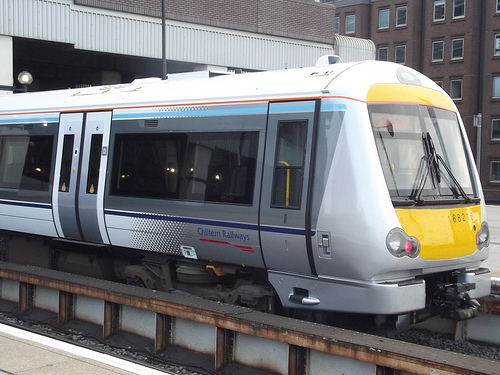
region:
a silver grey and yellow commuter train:
[0, 50, 496, 335]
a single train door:
[259, 100, 319, 276]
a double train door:
[50, 108, 112, 246]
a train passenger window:
[182, 131, 254, 204]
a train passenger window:
[112, 131, 182, 198]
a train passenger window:
[2, 134, 50, 190]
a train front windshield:
[371, 105, 476, 199]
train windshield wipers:
[410, 131, 472, 203]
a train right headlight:
[387, 232, 404, 251]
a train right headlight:
[481, 224, 489, 243]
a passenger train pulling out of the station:
[1, 39, 493, 345]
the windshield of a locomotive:
[369, 107, 476, 202]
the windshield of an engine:
[367, 103, 478, 205]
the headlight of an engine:
[386, 227, 406, 259]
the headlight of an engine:
[473, 218, 489, 247]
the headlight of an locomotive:
[383, 229, 406, 260]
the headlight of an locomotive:
[473, 223, 488, 248]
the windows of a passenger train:
[115, 135, 254, 207]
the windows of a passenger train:
[0, 123, 54, 193]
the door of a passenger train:
[261, 103, 318, 284]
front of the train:
[383, 77, 485, 252]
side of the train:
[12, 102, 315, 279]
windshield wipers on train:
[391, 150, 479, 203]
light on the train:
[370, 210, 410, 269]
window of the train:
[95, 123, 264, 202]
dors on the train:
[55, 90, 110, 249]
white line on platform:
[32, 315, 99, 365]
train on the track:
[5, 212, 475, 362]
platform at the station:
[10, 325, 55, 371]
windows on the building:
[361, 3, 448, 56]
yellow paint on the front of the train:
[346, 70, 491, 285]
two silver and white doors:
[45, 106, 122, 251]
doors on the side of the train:
[45, 105, 121, 250]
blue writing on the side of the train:
[185, 220, 260, 240]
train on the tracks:
[1, 28, 488, 373]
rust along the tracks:
[3, 265, 463, 373]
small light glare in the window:
[209, 168, 224, 183]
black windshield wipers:
[403, 129, 473, 201]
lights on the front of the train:
[381, 225, 425, 256]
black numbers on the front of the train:
[443, 210, 468, 226]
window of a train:
[105, 127, 262, 205]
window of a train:
[272, 119, 307, 209]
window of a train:
[370, 104, 476, 206]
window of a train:
[85, 133, 102, 195]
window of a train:
[58, 135, 73, 195]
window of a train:
[0, 121, 57, 199]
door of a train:
[260, 99, 322, 272]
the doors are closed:
[52, 107, 113, 240]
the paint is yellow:
[393, 203, 484, 258]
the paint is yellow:
[366, 82, 457, 107]